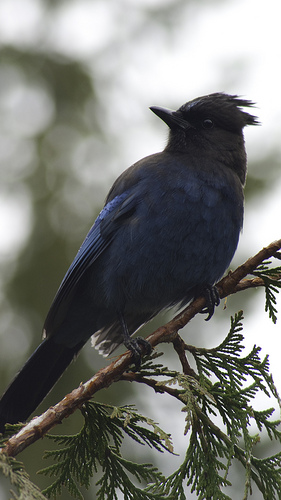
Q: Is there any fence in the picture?
A: No, there are no fences.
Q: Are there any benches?
A: No, there are no benches.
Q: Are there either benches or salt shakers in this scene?
A: No, there are no benches or salt shakers.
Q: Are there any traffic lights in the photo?
A: No, there are no traffic lights.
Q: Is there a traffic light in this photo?
A: No, there are no traffic lights.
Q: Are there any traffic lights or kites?
A: No, there are no traffic lights or kites.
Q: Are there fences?
A: No, there are no fences.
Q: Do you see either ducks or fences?
A: No, there are no fences or ducks.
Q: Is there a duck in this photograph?
A: No, there are no ducks.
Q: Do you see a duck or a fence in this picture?
A: No, there are no ducks or fences.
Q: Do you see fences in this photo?
A: No, there are no fences.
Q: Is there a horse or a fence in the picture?
A: No, there are no fences or horses.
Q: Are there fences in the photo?
A: No, there are no fences.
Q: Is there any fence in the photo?
A: No, there are no fences.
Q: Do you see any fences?
A: No, there are no fences.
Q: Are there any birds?
A: Yes, there is a bird.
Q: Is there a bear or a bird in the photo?
A: Yes, there is a bird.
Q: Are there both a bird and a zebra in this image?
A: No, there is a bird but no zebras.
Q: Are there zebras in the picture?
A: No, there are no zebras.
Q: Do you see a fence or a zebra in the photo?
A: No, there are no zebras or fences.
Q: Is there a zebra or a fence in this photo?
A: No, there are no zebras or fences.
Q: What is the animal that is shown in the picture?
A: The animal is a bird.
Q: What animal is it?
A: The animal is a bird.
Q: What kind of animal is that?
A: This is a bird.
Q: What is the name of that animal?
A: This is a bird.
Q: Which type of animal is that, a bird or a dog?
A: This is a bird.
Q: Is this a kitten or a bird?
A: This is a bird.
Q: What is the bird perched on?
A: The bird is perched on the branch.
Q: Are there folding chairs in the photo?
A: No, there are no folding chairs.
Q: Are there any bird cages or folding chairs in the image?
A: No, there are no folding chairs or bird cages.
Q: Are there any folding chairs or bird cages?
A: No, there are no folding chairs or bird cages.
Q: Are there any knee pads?
A: No, there are no knee pads.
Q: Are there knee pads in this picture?
A: No, there are no knee pads.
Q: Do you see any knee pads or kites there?
A: No, there are no knee pads or kites.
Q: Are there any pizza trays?
A: No, there are no pizza trays.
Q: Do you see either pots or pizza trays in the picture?
A: No, there are no pizza trays or pots.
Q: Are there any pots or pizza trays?
A: No, there are no pizza trays or pots.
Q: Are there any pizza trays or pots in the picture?
A: No, there are no pizza trays or pots.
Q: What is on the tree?
A: The leaves are on the tree.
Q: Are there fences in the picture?
A: No, there are no fences.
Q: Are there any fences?
A: No, there are no fences.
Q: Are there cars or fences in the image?
A: No, there are no fences or cars.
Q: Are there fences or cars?
A: No, there are no fences or cars.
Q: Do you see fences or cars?
A: No, there are no fences or cars.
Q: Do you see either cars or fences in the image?
A: No, there are no fences or cars.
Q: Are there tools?
A: No, there are no tools.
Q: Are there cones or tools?
A: No, there are no tools or cones.